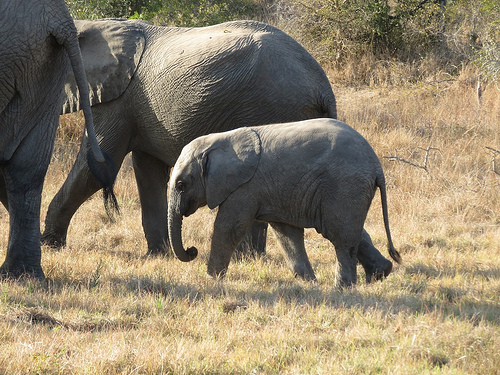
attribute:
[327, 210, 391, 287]
legs — hind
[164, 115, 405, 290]
elephant — baby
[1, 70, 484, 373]
grass — brown, dead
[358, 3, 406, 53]
grass — green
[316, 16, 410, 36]
grass — green